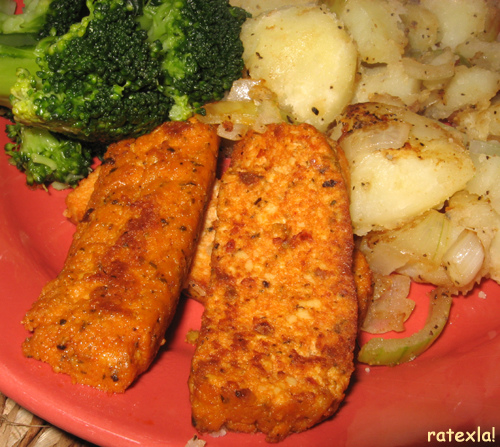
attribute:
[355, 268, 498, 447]
plate — red, round, singular, pink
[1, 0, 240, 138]
brocolli — green, plural, over-cooked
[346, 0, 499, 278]
potatoes — white, fried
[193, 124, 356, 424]
fish — oily, brown, greasy, fried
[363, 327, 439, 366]
onion — peppered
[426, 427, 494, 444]
watermark — present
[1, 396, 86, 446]
table — brown